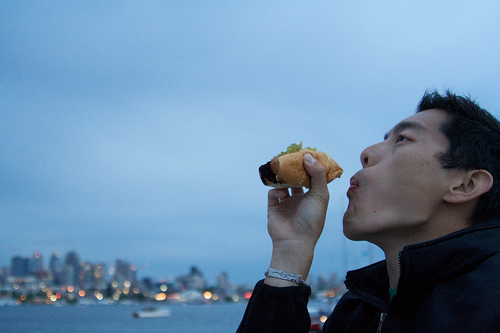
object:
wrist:
[264, 242, 315, 287]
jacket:
[233, 223, 500, 333]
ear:
[442, 170, 493, 204]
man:
[237, 88, 500, 333]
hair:
[414, 87, 500, 226]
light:
[13, 280, 104, 303]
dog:
[271, 159, 336, 184]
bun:
[258, 140, 343, 188]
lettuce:
[272, 140, 317, 159]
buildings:
[3, 247, 348, 305]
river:
[0, 303, 248, 333]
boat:
[134, 307, 174, 318]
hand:
[266, 153, 330, 241]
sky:
[0, 0, 500, 289]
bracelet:
[264, 268, 309, 287]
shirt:
[389, 287, 397, 303]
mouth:
[347, 176, 360, 195]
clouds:
[83, 108, 219, 224]